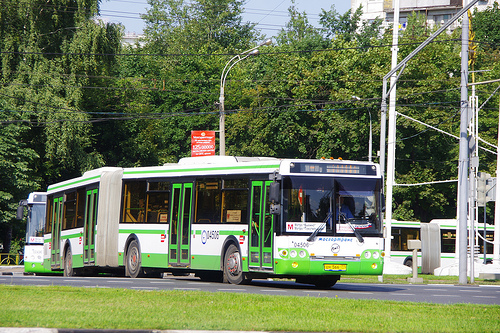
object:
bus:
[44, 153, 384, 285]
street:
[0, 272, 497, 305]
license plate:
[323, 264, 346, 272]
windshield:
[277, 175, 332, 233]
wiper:
[307, 211, 331, 242]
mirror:
[269, 181, 280, 205]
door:
[168, 182, 192, 266]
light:
[264, 39, 279, 46]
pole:
[220, 37, 272, 155]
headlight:
[295, 250, 308, 262]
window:
[218, 192, 251, 223]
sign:
[190, 129, 215, 158]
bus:
[19, 191, 50, 276]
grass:
[1, 284, 497, 333]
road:
[1, 274, 497, 306]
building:
[350, 0, 498, 38]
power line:
[0, 90, 465, 106]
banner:
[191, 130, 216, 158]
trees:
[1, 1, 500, 258]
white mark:
[389, 292, 416, 299]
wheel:
[218, 242, 247, 286]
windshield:
[333, 178, 384, 234]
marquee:
[301, 164, 362, 175]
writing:
[317, 235, 353, 243]